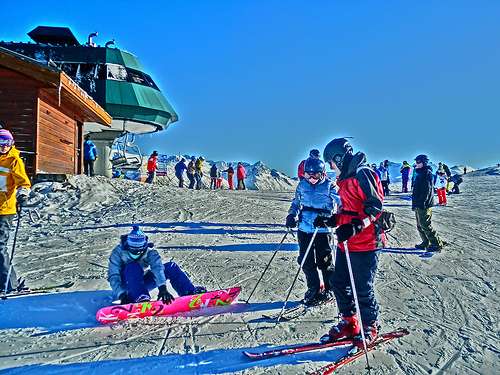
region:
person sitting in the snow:
[87, 217, 245, 326]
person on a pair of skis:
[245, 142, 347, 326]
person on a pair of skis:
[236, 129, 416, 374]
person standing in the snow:
[398, 153, 453, 256]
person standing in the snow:
[233, 159, 250, 190]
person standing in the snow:
[217, 160, 235, 192]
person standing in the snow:
[393, 155, 413, 195]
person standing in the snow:
[375, 160, 391, 192]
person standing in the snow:
[191, 153, 208, 190]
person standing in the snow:
[143, 148, 163, 184]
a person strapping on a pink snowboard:
[93, 219, 250, 326]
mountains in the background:
[153, 147, 285, 188]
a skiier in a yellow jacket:
[0, 121, 42, 301]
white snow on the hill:
[408, 253, 494, 359]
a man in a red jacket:
[319, 140, 404, 370]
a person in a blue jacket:
[301, 150, 338, 305]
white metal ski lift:
[104, 132, 146, 181]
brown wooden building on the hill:
[0, 58, 100, 182]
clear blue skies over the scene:
[281, 27, 451, 129]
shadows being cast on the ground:
[168, 202, 277, 256]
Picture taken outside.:
[22, 41, 446, 371]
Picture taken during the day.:
[18, 36, 490, 368]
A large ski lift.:
[83, 34, 170, 124]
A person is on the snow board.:
[77, 227, 244, 339]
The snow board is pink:
[88, 287, 250, 323]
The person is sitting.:
[108, 231, 186, 291]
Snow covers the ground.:
[69, 133, 494, 358]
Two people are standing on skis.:
[287, 116, 392, 346]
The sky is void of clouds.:
[191, 60, 323, 110]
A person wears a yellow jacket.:
[4, 159, 23, 216]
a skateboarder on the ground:
[95, 201, 250, 335]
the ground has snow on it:
[7, 152, 498, 370]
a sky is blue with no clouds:
[3, 1, 497, 201]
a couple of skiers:
[256, 128, 430, 373]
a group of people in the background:
[69, 119, 497, 217]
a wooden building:
[0, 39, 128, 189]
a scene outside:
[10, 11, 498, 366]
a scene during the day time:
[6, 8, 486, 372]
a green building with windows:
[0, 23, 182, 194]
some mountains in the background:
[79, 129, 499, 224]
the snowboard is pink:
[92, 298, 212, 319]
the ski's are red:
[252, 344, 315, 364]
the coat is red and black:
[341, 182, 360, 209]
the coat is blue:
[303, 189, 318, 218]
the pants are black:
[301, 244, 316, 280]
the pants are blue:
[121, 268, 144, 289]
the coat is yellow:
[8, 161, 28, 184]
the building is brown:
[36, 106, 66, 149]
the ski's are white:
[274, 297, 309, 327]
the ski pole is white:
[338, 250, 363, 302]